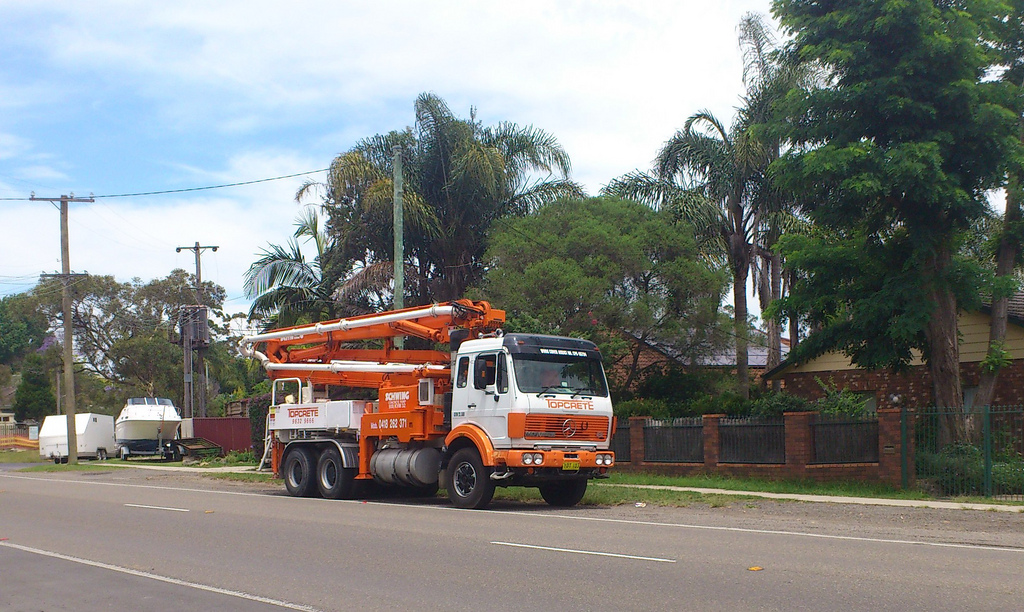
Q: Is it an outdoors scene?
A: Yes, it is outdoors.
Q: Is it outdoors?
A: Yes, it is outdoors.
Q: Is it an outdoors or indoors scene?
A: It is outdoors.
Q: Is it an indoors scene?
A: No, it is outdoors.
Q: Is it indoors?
A: No, it is outdoors.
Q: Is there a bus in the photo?
A: No, there are no buses.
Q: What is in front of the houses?
A: The trees are in front of the houses.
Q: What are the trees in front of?
A: The trees are in front of the houses.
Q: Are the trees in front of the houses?
A: Yes, the trees are in front of the houses.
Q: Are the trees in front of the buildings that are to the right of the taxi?
A: Yes, the trees are in front of the houses.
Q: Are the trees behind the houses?
A: No, the trees are in front of the houses.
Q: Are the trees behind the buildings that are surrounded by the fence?
A: No, the trees are in front of the houses.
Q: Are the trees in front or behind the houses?
A: The trees are in front of the houses.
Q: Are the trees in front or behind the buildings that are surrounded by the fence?
A: The trees are in front of the houses.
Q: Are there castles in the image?
A: No, there are no castles.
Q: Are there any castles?
A: No, there are no castles.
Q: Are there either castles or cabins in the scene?
A: No, there are no castles or cabins.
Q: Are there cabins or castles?
A: No, there are no castles or cabins.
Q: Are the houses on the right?
A: Yes, the houses are on the right of the image.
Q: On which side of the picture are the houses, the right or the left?
A: The houses are on the right of the image.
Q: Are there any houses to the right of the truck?
A: Yes, there are houses to the right of the truck.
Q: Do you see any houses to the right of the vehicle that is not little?
A: Yes, there are houses to the right of the truck.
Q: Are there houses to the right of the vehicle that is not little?
A: Yes, there are houses to the right of the truck.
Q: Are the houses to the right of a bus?
A: No, the houses are to the right of the truck.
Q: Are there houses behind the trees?
A: Yes, there are houses behind the trees.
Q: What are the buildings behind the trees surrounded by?
A: The houses are surrounded by the fence.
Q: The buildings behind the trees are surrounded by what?
A: The houses are surrounded by the fence.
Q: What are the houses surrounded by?
A: The houses are surrounded by the fence.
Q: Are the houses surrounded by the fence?
A: Yes, the houses are surrounded by the fence.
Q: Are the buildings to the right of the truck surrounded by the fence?
A: Yes, the houses are surrounded by the fence.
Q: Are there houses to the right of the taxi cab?
A: Yes, there are houses to the right of the taxi cab.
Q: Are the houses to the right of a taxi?
A: Yes, the houses are to the right of a taxi.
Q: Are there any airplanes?
A: No, there are no airplanes.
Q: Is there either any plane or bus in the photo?
A: No, there are no airplanes or buses.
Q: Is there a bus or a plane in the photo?
A: No, there are no airplanes or buses.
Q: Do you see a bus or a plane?
A: No, there are no airplanes or buses.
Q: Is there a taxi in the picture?
A: Yes, there is a taxi.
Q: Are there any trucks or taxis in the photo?
A: Yes, there is a taxi.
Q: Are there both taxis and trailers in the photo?
A: Yes, there are both a taxi and a trailer.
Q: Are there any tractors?
A: No, there are no tractors.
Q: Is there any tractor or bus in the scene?
A: No, there are no tractors or buses.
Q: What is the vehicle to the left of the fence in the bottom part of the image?
A: The vehicle is a taxi.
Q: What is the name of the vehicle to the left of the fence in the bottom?
A: The vehicle is a taxi.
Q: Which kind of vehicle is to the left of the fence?
A: The vehicle is a taxi.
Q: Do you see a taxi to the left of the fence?
A: Yes, there is a taxi to the left of the fence.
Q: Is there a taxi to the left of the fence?
A: Yes, there is a taxi to the left of the fence.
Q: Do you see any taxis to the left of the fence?
A: Yes, there is a taxi to the left of the fence.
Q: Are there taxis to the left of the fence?
A: Yes, there is a taxi to the left of the fence.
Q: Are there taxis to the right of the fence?
A: No, the taxi is to the left of the fence.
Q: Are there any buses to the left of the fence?
A: No, there is a taxi to the left of the fence.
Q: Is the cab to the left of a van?
A: No, the cab is to the left of a fence.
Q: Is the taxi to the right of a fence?
A: No, the taxi is to the left of a fence.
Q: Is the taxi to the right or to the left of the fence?
A: The taxi is to the left of the fence.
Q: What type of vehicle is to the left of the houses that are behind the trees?
A: The vehicle is a taxi.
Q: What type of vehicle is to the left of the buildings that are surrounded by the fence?
A: The vehicle is a taxi.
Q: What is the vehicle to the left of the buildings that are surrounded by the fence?
A: The vehicle is a taxi.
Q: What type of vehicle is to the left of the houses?
A: The vehicle is a taxi.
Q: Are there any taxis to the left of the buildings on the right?
A: Yes, there is a taxi to the left of the houses.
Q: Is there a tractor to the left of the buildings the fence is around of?
A: No, there is a taxi to the left of the houses.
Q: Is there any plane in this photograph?
A: No, there are no airplanes.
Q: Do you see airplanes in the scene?
A: No, there are no airplanes.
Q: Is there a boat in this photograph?
A: Yes, there is a boat.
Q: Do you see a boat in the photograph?
A: Yes, there is a boat.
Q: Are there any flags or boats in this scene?
A: Yes, there is a boat.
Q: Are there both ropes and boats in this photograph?
A: No, there is a boat but no ropes.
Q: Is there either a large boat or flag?
A: Yes, there is a large boat.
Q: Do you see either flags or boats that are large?
A: Yes, the boat is large.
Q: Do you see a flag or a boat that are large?
A: Yes, the boat is large.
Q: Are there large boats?
A: Yes, there is a large boat.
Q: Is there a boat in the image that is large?
A: Yes, there is a boat that is large.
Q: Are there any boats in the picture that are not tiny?
A: Yes, there is a large boat.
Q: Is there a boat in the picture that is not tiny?
A: Yes, there is a large boat.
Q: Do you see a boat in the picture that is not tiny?
A: Yes, there is a large boat.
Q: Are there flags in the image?
A: No, there are no flags.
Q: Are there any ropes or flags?
A: No, there are no flags or ropes.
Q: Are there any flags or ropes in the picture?
A: No, there are no flags or ropes.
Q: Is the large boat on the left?
A: Yes, the boat is on the left of the image.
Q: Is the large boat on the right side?
A: No, the boat is on the left of the image.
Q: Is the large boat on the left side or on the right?
A: The boat is on the left of the image.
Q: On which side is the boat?
A: The boat is on the left of the image.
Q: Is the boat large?
A: Yes, the boat is large.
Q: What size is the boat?
A: The boat is large.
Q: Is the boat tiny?
A: No, the boat is large.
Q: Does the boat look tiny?
A: No, the boat is large.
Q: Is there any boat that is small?
A: No, there is a boat but it is large.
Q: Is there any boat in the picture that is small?
A: No, there is a boat but it is large.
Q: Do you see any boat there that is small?
A: No, there is a boat but it is large.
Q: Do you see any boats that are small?
A: No, there is a boat but it is large.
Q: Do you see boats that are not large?
A: No, there is a boat but it is large.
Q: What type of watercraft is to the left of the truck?
A: The watercraft is a boat.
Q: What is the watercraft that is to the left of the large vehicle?
A: The watercraft is a boat.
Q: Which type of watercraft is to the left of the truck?
A: The watercraft is a boat.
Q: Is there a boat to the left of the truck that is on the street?
A: Yes, there is a boat to the left of the truck.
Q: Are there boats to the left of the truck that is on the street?
A: Yes, there is a boat to the left of the truck.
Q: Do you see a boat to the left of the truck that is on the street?
A: Yes, there is a boat to the left of the truck.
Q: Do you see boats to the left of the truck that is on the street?
A: Yes, there is a boat to the left of the truck.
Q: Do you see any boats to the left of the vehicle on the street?
A: Yes, there is a boat to the left of the truck.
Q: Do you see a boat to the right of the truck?
A: No, the boat is to the left of the truck.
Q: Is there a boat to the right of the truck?
A: No, the boat is to the left of the truck.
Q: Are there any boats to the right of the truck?
A: No, the boat is to the left of the truck.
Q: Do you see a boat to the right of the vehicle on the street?
A: No, the boat is to the left of the truck.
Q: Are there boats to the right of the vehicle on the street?
A: No, the boat is to the left of the truck.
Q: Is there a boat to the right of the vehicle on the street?
A: No, the boat is to the left of the truck.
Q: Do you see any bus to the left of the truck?
A: No, there is a boat to the left of the truck.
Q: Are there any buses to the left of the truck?
A: No, there is a boat to the left of the truck.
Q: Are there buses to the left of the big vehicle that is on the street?
A: No, there is a boat to the left of the truck.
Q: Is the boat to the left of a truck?
A: Yes, the boat is to the left of a truck.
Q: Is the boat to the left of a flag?
A: No, the boat is to the left of a truck.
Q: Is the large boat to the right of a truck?
A: No, the boat is to the left of a truck.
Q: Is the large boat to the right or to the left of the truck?
A: The boat is to the left of the truck.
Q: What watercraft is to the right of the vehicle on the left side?
A: The watercraft is a boat.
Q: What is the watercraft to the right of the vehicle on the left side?
A: The watercraft is a boat.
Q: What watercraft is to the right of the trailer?
A: The watercraft is a boat.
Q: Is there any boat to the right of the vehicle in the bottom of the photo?
A: Yes, there is a boat to the right of the trailer.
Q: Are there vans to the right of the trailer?
A: No, there is a boat to the right of the trailer.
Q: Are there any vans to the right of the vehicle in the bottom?
A: No, there is a boat to the right of the trailer.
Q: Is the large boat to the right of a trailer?
A: Yes, the boat is to the right of a trailer.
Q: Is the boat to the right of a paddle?
A: No, the boat is to the right of a trailer.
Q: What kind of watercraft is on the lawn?
A: The watercraft is a boat.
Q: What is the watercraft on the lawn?
A: The watercraft is a boat.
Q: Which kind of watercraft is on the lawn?
A: The watercraft is a boat.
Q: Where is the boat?
A: The boat is on the lawn.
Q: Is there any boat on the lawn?
A: Yes, there is a boat on the lawn.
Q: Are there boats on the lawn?
A: Yes, there is a boat on the lawn.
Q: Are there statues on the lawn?
A: No, there is a boat on the lawn.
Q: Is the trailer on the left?
A: Yes, the trailer is on the left of the image.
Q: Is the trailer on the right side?
A: No, the trailer is on the left of the image.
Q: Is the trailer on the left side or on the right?
A: The trailer is on the left of the image.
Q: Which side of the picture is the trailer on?
A: The trailer is on the left of the image.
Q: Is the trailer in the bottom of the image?
A: Yes, the trailer is in the bottom of the image.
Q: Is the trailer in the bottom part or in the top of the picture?
A: The trailer is in the bottom of the image.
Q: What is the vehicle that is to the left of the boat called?
A: The vehicle is a trailer.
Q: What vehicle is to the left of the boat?
A: The vehicle is a trailer.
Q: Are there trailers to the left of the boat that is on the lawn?
A: Yes, there is a trailer to the left of the boat.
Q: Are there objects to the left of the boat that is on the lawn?
A: No, there is a trailer to the left of the boat.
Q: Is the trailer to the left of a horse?
A: No, the trailer is to the left of the boat.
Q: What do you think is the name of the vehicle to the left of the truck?
A: The vehicle is a trailer.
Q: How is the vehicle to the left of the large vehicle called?
A: The vehicle is a trailer.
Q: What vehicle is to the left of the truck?
A: The vehicle is a trailer.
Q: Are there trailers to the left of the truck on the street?
A: Yes, there is a trailer to the left of the truck.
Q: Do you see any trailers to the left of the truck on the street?
A: Yes, there is a trailer to the left of the truck.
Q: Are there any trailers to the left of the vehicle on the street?
A: Yes, there is a trailer to the left of the truck.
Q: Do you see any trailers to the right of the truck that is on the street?
A: No, the trailer is to the left of the truck.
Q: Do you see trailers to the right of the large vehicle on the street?
A: No, the trailer is to the left of the truck.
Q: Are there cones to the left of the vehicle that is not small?
A: No, there is a trailer to the left of the truck.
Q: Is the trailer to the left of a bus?
A: No, the trailer is to the left of the truck.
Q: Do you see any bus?
A: No, there are no buses.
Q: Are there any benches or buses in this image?
A: No, there are no buses or benches.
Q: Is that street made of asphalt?
A: Yes, the street is made of asphalt.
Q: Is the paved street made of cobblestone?
A: No, the street is made of asphalt.